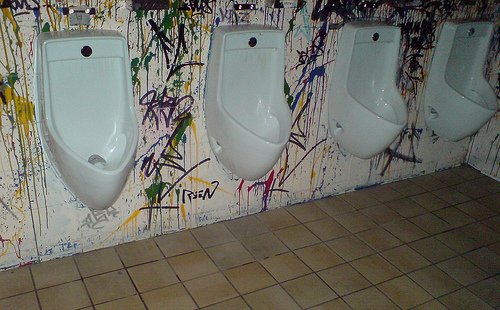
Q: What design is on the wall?
A: Paint splatters.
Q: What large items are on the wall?
A: Urinals.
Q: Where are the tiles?
A: On the ground.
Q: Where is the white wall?
A: Under paint splatters.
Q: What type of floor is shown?
A: Tile.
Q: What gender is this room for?
A: Male.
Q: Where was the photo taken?
A: Bathroom.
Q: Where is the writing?
A: On wall.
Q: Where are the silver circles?
A: On urinals.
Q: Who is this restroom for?
A: Males.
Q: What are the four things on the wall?
A: Urinals.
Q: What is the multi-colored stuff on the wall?
A: Graffiti.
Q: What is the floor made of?
A: Tile.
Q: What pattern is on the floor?
A: Squares.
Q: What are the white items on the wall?
A: Urinals.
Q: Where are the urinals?
A: On the wall.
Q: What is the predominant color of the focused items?
A: White.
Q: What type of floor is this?
A: Tile.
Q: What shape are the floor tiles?
A: Square.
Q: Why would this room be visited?
A: To go to the bathroom.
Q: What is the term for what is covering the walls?
A: Graffiti.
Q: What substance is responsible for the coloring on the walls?
A: Paint.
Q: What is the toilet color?
A: White.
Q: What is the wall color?
A: White.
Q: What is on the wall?
A: Graffiti.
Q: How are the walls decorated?
A: In colorful paint.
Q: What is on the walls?
A: Urinals.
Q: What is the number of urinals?
A: Four.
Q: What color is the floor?
A: Brown.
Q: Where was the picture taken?
A: In a bathroom.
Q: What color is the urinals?
A: White.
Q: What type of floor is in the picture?
A: Tiled.